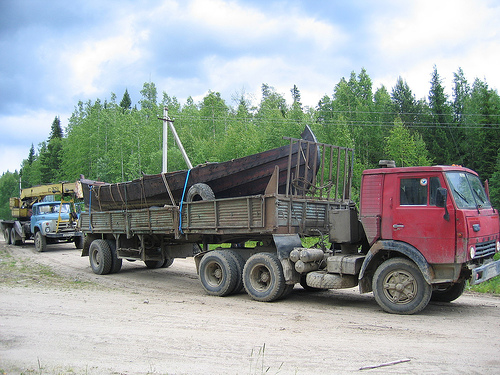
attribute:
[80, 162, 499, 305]
truck — parked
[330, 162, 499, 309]
cab — dirty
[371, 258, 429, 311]
wheel — dirty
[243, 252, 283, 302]
wheel — dirty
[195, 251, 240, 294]
wheel — dirty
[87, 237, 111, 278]
wheel — dirty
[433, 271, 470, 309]
wheel — dirty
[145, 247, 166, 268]
wheel — dirty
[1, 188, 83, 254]
truck — old, blue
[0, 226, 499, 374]
road — muddy, dirt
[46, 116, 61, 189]
tree — evergreen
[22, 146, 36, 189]
tree — evergreen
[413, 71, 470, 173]
tree — evergreen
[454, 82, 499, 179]
tree — evergreen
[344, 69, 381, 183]
tree — evergreen